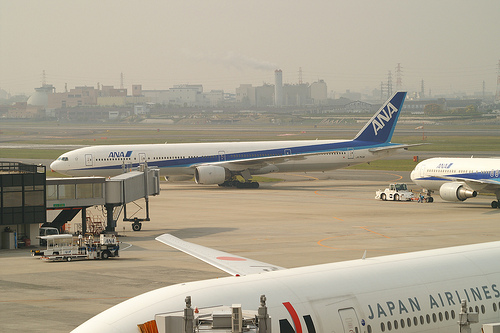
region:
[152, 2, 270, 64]
a grey sky.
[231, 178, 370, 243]
a clean clear ground.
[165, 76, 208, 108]
a beige brick building.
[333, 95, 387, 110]
a big bridge.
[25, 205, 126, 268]
a white business truck.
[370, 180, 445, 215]
a toad truck to move planes.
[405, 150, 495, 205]
a white and blue plane.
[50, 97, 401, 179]
a plane from ana.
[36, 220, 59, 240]
a truck parked inside the lot.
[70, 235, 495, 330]
a plane from japan airlines.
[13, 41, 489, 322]
This is an airport scene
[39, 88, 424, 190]
A passenger jet is on the runway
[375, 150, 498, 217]
This jet is being towed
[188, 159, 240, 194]
One of the jet's engines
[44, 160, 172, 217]
An aircraft boarding gate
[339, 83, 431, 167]
The plane's tail section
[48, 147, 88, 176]
The plane's nose section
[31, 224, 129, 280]
A baggage hauling vehicle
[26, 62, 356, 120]
Buildings are in the distance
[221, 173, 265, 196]
The rear landing gears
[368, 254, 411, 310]
the plane is white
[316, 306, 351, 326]
the plane is white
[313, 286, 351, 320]
the plane is white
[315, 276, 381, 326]
the plane is white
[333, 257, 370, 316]
the plane is white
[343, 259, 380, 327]
the plane is white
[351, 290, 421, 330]
green letters that say japan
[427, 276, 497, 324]
green letters that say airlines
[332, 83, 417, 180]
blue and white tale of a plane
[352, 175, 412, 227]
a white truck on conrcrete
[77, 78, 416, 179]
a blue and white plane that says ana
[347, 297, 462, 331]
small windows of a airplane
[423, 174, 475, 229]
a engine of a plane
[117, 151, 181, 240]
tire on a loading platform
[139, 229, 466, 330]
a red and white airplane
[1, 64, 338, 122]
a city in the back ground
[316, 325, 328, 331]
the plane is white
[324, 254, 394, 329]
the plane is white